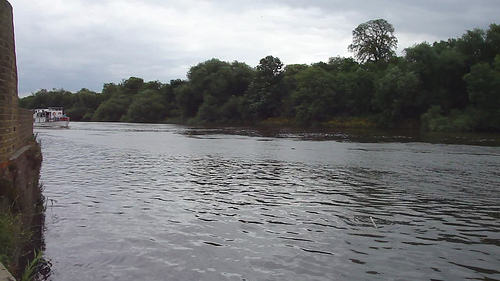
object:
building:
[29, 106, 70, 122]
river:
[33, 121, 499, 281]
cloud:
[45, 43, 118, 73]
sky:
[8, 0, 500, 99]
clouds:
[6, 1, 496, 98]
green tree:
[347, 19, 398, 69]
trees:
[365, 63, 404, 128]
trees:
[287, 66, 344, 124]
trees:
[243, 54, 290, 120]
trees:
[186, 59, 254, 128]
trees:
[461, 61, 497, 131]